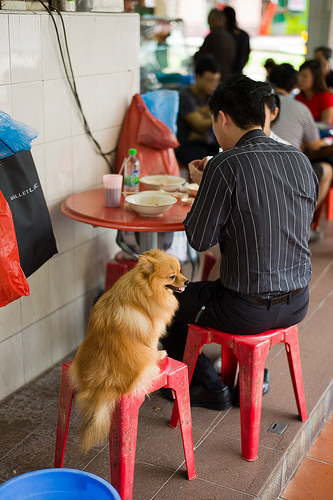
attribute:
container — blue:
[2, 467, 119, 499]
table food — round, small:
[60, 170, 183, 231]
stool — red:
[221, 330, 275, 385]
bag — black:
[1, 130, 59, 311]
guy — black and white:
[162, 72, 318, 410]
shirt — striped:
[182, 129, 319, 294]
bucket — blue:
[0, 466, 124, 498]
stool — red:
[187, 310, 304, 456]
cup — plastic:
[102, 174, 123, 210]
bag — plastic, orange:
[0, 188, 30, 307]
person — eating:
[178, 56, 219, 163]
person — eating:
[267, 62, 330, 220]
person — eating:
[294, 59, 332, 132]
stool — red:
[52, 352, 204, 498]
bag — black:
[0, 110, 59, 280]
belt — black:
[220, 280, 310, 304]